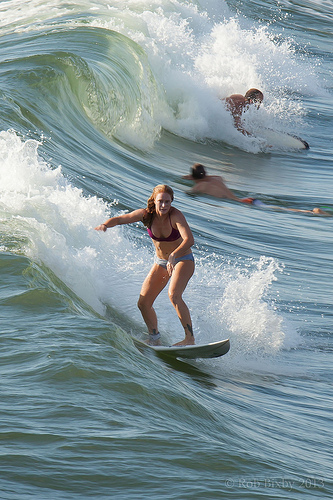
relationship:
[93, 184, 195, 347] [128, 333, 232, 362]
girl getting up on a surfboard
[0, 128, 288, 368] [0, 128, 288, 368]
foam waves on foam waves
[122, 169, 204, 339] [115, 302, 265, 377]
girl on surfboard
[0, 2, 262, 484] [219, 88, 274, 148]
wave over person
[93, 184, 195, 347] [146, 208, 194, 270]
girl wearing bikini top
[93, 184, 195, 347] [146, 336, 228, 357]
girl standing on surfboard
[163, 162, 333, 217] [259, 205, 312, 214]
man swimming lying on surfboard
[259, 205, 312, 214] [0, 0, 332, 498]
surfboard in water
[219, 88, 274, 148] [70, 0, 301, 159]
person being splashed by wave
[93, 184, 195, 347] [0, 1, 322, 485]
girl riding wave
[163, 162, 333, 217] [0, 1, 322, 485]
man swimming riding wave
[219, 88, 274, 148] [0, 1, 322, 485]
person riding wave